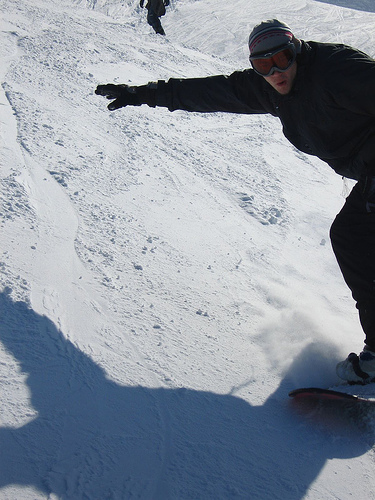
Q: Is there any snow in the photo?
A: Yes, there is snow.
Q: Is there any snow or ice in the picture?
A: Yes, there is snow.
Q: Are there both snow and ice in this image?
A: No, there is snow but no ice.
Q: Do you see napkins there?
A: No, there are no napkins.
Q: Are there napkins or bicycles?
A: No, there are no napkins or bicycles.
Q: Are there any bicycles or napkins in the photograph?
A: No, there are no napkins or bicycles.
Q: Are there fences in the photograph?
A: No, there are no fences.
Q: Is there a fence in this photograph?
A: No, there are no fences.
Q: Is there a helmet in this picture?
A: No, there are no helmets.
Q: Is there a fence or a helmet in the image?
A: No, there are no helmets or fences.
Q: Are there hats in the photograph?
A: Yes, there is a hat.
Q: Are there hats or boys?
A: Yes, there is a hat.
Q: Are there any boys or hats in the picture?
A: Yes, there is a hat.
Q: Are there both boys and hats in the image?
A: No, there is a hat but no boys.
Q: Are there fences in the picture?
A: No, there are no fences.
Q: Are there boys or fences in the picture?
A: No, there are no fences or boys.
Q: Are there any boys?
A: No, there are no boys.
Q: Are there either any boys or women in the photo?
A: No, there are no boys or women.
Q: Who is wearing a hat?
A: The man is wearing a hat.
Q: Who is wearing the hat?
A: The man is wearing a hat.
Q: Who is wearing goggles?
A: The man is wearing goggles.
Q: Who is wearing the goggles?
A: The man is wearing goggles.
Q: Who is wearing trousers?
A: The man is wearing trousers.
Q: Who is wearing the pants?
A: The man is wearing trousers.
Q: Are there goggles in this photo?
A: Yes, there are goggles.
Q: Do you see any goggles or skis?
A: Yes, there are goggles.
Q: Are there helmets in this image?
A: No, there are no helmets.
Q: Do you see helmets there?
A: No, there are no helmets.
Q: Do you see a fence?
A: No, there are no fences.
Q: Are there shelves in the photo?
A: No, there are no shelves.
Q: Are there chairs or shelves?
A: No, there are no shelves or chairs.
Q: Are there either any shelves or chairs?
A: No, there are no shelves or chairs.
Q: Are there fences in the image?
A: No, there are no fences.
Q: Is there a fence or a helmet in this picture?
A: No, there are no fences or helmets.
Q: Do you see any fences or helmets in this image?
A: No, there are no fences or helmets.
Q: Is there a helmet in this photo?
A: No, there are no helmets.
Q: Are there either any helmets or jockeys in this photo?
A: No, there are no helmets or jockeys.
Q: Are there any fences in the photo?
A: No, there are no fences.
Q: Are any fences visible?
A: No, there are no fences.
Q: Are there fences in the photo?
A: No, there are no fences.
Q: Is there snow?
A: Yes, there is snow.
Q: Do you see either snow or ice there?
A: Yes, there is snow.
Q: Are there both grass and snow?
A: No, there is snow but no grass.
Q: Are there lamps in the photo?
A: No, there are no lamps.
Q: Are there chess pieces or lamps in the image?
A: No, there are no lamps or chess pieces.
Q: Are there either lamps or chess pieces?
A: No, there are no lamps or chess pieces.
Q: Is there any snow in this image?
A: Yes, there is snow.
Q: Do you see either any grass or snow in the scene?
A: Yes, there is snow.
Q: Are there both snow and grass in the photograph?
A: No, there is snow but no grass.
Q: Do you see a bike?
A: No, there are no bikes.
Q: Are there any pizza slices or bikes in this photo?
A: No, there are no bikes or pizza slices.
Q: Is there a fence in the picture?
A: No, there are no fences.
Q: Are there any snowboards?
A: Yes, there is a snowboard.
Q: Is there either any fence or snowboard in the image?
A: Yes, there is a snowboard.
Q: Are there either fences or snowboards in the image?
A: Yes, there is a snowboard.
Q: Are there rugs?
A: No, there are no rugs.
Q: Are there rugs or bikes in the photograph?
A: No, there are no rugs or bikes.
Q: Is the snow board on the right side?
A: Yes, the snow board is on the right of the image.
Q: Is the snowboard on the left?
A: No, the snowboard is on the right of the image.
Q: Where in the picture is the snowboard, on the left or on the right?
A: The snowboard is on the right of the image.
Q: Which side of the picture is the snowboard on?
A: The snowboard is on the right of the image.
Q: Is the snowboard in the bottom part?
A: Yes, the snowboard is in the bottom of the image.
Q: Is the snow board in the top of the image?
A: No, the snow board is in the bottom of the image.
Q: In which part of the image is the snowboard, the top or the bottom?
A: The snowboard is in the bottom of the image.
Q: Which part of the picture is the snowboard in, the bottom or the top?
A: The snowboard is in the bottom of the image.